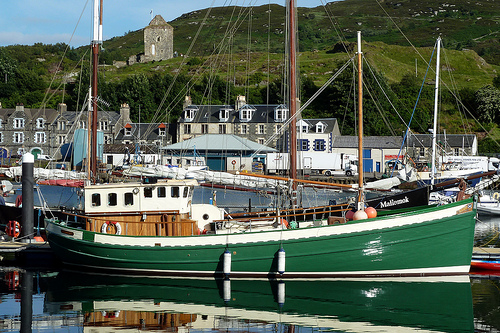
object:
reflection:
[10, 276, 469, 331]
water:
[308, 286, 354, 305]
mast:
[329, 112, 404, 208]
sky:
[33, 3, 202, 40]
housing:
[41, 180, 205, 229]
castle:
[130, 18, 173, 60]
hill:
[100, 34, 268, 98]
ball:
[361, 200, 382, 229]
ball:
[351, 206, 367, 224]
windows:
[86, 187, 137, 214]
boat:
[47, 219, 476, 282]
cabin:
[79, 160, 227, 244]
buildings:
[143, 19, 173, 63]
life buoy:
[99, 218, 121, 237]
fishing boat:
[37, 179, 469, 290]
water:
[40, 277, 486, 331]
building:
[7, 110, 472, 155]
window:
[183, 121, 192, 135]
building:
[181, 101, 291, 153]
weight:
[220, 249, 235, 279]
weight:
[272, 242, 291, 282]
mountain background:
[4, 0, 493, 109]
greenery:
[182, 25, 437, 99]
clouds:
[3, 29, 82, 46]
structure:
[139, 11, 183, 63]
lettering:
[376, 192, 415, 210]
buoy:
[348, 202, 376, 221]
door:
[372, 159, 382, 179]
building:
[333, 130, 423, 176]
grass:
[200, 23, 271, 93]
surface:
[110, 12, 492, 141]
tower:
[131, 2, 181, 71]